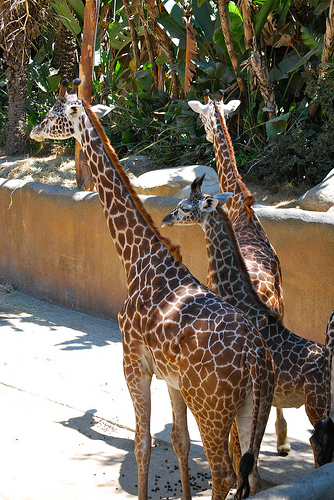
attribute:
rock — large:
[300, 172, 332, 208]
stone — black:
[156, 475, 159, 477]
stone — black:
[197, 485, 201, 487]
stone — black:
[165, 458, 169, 462]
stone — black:
[157, 495, 161, 498]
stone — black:
[195, 470, 200, 474]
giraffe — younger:
[170, 175, 264, 288]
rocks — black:
[161, 462, 209, 489]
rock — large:
[125, 161, 230, 199]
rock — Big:
[273, 165, 333, 209]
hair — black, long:
[311, 418, 332, 465]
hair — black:
[237, 451, 256, 497]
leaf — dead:
[179, 12, 197, 95]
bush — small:
[256, 123, 324, 175]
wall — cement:
[1, 175, 323, 339]